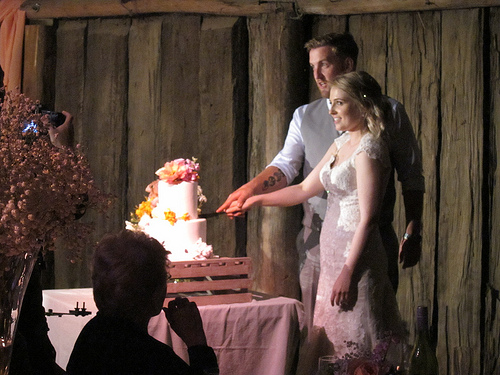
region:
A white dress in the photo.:
[310, 134, 395, 356]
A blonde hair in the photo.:
[333, 73, 388, 126]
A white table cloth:
[213, 295, 295, 351]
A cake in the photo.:
[136, 155, 212, 253]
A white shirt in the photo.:
[278, 102, 330, 171]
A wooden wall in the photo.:
[435, 56, 497, 230]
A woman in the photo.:
[314, 76, 404, 356]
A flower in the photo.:
[0, 89, 83, 246]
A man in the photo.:
[268, 38, 419, 179]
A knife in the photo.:
[197, 205, 245, 222]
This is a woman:
[325, 75, 425, 372]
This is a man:
[287, 33, 359, 328]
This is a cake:
[150, 142, 214, 186]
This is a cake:
[144, 176, 211, 203]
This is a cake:
[150, 201, 210, 225]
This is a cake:
[155, 225, 233, 265]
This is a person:
[74, 223, 198, 370]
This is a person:
[327, 73, 408, 354]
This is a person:
[292, 22, 364, 247]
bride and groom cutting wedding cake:
[121, 31, 428, 371]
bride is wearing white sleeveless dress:
[231, 69, 397, 371]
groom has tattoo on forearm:
[211, 26, 365, 216]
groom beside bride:
[218, 30, 428, 362]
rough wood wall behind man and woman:
[39, 15, 497, 367]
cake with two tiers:
[130, 156, 212, 260]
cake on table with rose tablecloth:
[39, 152, 311, 373]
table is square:
[39, 276, 301, 373]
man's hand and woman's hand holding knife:
[201, 190, 250, 220]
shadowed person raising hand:
[66, 230, 220, 373]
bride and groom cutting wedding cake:
[127, 8, 432, 346]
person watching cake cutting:
[76, 236, 201, 357]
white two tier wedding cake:
[120, 166, 217, 256]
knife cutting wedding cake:
[201, 203, 226, 225]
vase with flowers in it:
[2, 97, 87, 372]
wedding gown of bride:
[310, 140, 400, 372]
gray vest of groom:
[294, 101, 387, 176]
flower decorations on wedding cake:
[129, 148, 204, 226]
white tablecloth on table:
[50, 278, 290, 374]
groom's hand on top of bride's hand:
[214, 183, 249, 218]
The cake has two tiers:
[122, 155, 220, 257]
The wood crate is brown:
[171, 259, 261, 305]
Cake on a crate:
[128, 155, 258, 306]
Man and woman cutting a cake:
[132, 32, 419, 374]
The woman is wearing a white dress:
[303, 67, 391, 359]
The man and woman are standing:
[204, 34, 431, 369]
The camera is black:
[14, 97, 82, 160]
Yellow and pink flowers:
[127, 153, 212, 261]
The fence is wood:
[33, 14, 490, 361]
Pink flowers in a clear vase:
[3, 97, 73, 351]